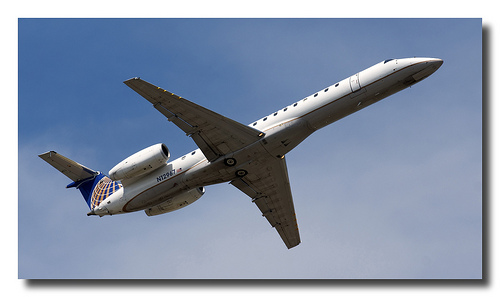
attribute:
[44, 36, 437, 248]
plane — sky, Door , tail , window , large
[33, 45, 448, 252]
plane — Numbers , Engine, Windows, white, large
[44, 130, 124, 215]
tail — Circle with lines 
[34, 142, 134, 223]
tail — blue, Background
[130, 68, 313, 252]
wing — white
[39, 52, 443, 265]
plane — Windshield 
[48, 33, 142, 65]
sky — blue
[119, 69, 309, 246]
plane — wing 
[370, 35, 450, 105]
plane — nose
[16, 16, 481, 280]
sky — clear, blue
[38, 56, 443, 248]
airplane — large, white